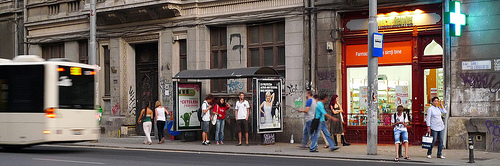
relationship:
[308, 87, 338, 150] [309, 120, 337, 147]
man wearing blue jeans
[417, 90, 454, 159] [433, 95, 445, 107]
woman talking on cellphone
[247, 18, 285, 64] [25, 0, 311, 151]
window of building